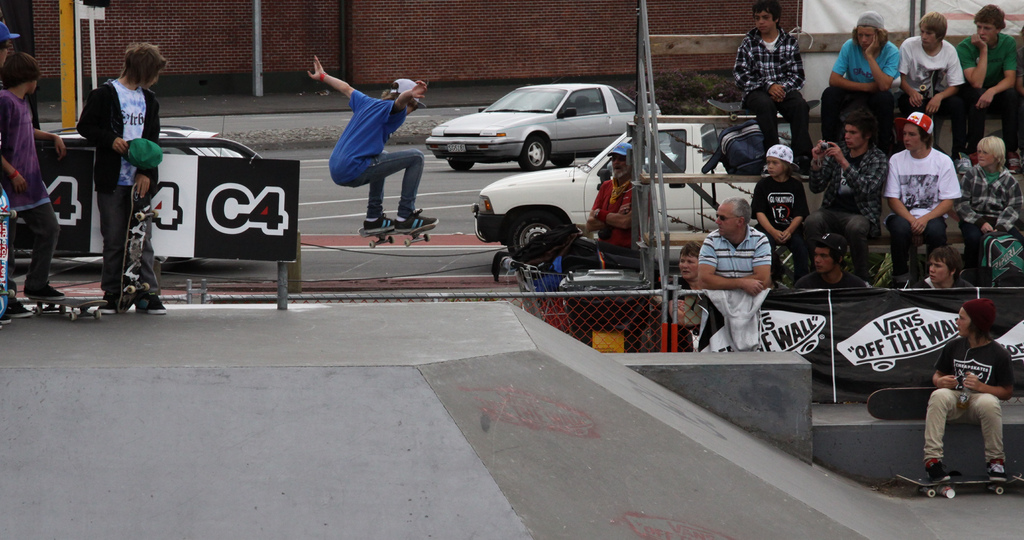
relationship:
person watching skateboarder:
[910, 288, 1021, 503] [312, 29, 459, 259]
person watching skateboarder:
[904, 247, 982, 314] [281, 41, 491, 255]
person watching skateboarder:
[793, 232, 843, 293] [290, 48, 470, 252]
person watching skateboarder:
[670, 188, 798, 359] [292, 52, 480, 266]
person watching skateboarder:
[670, 242, 703, 309] [296, 31, 457, 258]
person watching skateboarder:
[794, 104, 903, 264] [309, 46, 474, 263]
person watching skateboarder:
[878, 108, 971, 277] [268, 31, 513, 276]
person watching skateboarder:
[940, 113, 1021, 276] [303, 35, 476, 254]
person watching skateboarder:
[754, 124, 815, 282] [309, 24, 498, 269]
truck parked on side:
[458, 109, 794, 235] [498, 249, 792, 314]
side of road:
[498, 249, 792, 314] [251, 108, 520, 258]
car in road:
[413, 54, 681, 160] [281, 130, 580, 236]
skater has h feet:
[904, 294, 1021, 483] [906, 437, 1012, 476]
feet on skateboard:
[906, 437, 1012, 476] [889, 459, 1021, 503]